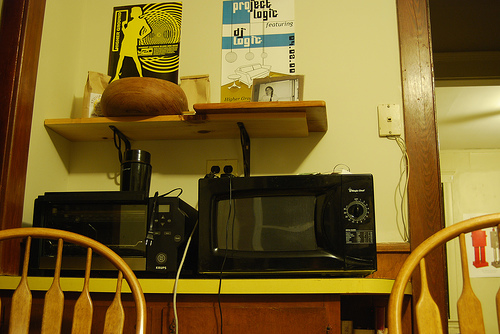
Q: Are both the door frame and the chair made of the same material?
A: Yes, both the door frame and the chair are made of wood.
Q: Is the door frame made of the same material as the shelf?
A: Yes, both the door frame and the shelf are made of wood.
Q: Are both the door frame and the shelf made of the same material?
A: Yes, both the door frame and the shelf are made of wood.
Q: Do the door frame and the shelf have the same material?
A: Yes, both the door frame and the shelf are made of wood.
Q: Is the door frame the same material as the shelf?
A: Yes, both the door frame and the shelf are made of wood.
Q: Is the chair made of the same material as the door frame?
A: Yes, both the chair and the door frame are made of wood.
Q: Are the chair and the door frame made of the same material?
A: Yes, both the chair and the door frame are made of wood.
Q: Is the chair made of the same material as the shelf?
A: Yes, both the chair and the shelf are made of wood.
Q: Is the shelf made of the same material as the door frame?
A: Yes, both the shelf and the door frame are made of wood.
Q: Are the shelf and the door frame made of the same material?
A: Yes, both the shelf and the door frame are made of wood.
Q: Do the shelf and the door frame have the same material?
A: Yes, both the shelf and the door frame are made of wood.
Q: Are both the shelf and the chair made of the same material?
A: Yes, both the shelf and the chair are made of wood.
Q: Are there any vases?
A: No, there are no vases.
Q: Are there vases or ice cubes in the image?
A: No, there are no vases or ice cubes.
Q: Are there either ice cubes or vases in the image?
A: No, there are no vases or ice cubes.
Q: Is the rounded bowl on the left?
A: Yes, the bowl is on the left of the image.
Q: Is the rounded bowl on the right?
A: No, the bowl is on the left of the image.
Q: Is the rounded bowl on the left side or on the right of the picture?
A: The bowl is on the left of the image.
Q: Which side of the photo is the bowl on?
A: The bowl is on the left of the image.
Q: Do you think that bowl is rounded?
A: Yes, the bowl is rounded.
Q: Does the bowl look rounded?
A: Yes, the bowl is rounded.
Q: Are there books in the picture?
A: No, there are no books.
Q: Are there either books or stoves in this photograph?
A: No, there are no books or stoves.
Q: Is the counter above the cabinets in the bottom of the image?
A: Yes, the counter is above the cabinets.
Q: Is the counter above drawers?
A: No, the counter is above the cabinets.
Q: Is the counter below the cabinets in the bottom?
A: No, the counter is above the cabinets.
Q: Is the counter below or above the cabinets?
A: The counter is above the cabinets.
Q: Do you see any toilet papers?
A: No, there are no toilet papers.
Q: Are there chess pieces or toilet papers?
A: No, there are no toilet papers or chess pieces.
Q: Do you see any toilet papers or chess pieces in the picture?
A: No, there are no toilet papers or chess pieces.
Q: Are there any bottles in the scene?
A: No, there are no bottles.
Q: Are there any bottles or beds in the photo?
A: No, there are no bottles or beds.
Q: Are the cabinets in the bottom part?
A: Yes, the cabinets are in the bottom of the image.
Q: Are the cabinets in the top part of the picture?
A: No, the cabinets are in the bottom of the image.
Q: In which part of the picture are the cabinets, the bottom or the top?
A: The cabinets are in the bottom of the image.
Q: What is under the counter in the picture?
A: The cabinets are under the counter.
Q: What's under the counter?
A: The cabinets are under the counter.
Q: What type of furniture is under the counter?
A: The pieces of furniture are cabinets.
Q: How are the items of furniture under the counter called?
A: The pieces of furniture are cabinets.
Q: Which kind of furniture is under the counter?
A: The pieces of furniture are cabinets.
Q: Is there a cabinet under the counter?
A: Yes, there are cabinets under the counter.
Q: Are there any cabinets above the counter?
A: No, the cabinets are under the counter.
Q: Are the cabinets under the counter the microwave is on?
A: Yes, the cabinets are under the counter.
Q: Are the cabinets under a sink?
A: No, the cabinets are under the counter.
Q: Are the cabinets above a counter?
A: No, the cabinets are under a counter.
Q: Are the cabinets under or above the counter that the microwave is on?
A: The cabinets are under the counter.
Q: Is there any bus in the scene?
A: No, there are no buses.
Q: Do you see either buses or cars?
A: No, there are no buses or cars.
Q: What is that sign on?
A: The sign is on the wall.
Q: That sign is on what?
A: The sign is on the wall.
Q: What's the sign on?
A: The sign is on the wall.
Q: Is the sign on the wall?
A: Yes, the sign is on the wall.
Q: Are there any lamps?
A: No, there are no lamps.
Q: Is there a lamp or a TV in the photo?
A: No, there are no lamps or televisions.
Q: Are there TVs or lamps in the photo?
A: No, there are no lamps or tvs.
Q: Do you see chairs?
A: Yes, there is a chair.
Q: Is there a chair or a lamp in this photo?
A: Yes, there is a chair.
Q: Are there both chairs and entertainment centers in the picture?
A: No, there is a chair but no entertainment centers.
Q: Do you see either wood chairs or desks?
A: Yes, there is a wood chair.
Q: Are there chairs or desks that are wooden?
A: Yes, the chair is wooden.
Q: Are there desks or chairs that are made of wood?
A: Yes, the chair is made of wood.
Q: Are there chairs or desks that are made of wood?
A: Yes, the chair is made of wood.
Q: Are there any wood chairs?
A: Yes, there is a wood chair.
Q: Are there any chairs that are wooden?
A: Yes, there is a chair that is wooden.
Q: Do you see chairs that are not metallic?
A: Yes, there is a wooden chair.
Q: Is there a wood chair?
A: Yes, there is a chair that is made of wood.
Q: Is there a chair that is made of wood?
A: Yes, there is a chair that is made of wood.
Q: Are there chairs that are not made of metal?
A: Yes, there is a chair that is made of wood.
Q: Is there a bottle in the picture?
A: No, there are no bottles.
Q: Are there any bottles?
A: No, there are no bottles.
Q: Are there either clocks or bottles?
A: No, there are no bottles or clocks.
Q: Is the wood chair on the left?
A: Yes, the chair is on the left of the image.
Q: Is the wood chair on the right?
A: No, the chair is on the left of the image.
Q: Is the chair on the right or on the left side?
A: The chair is on the left of the image.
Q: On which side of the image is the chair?
A: The chair is on the left of the image.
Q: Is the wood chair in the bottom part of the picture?
A: Yes, the chair is in the bottom of the image.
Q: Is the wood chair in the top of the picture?
A: No, the chair is in the bottom of the image.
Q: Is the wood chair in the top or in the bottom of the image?
A: The chair is in the bottom of the image.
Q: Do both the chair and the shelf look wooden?
A: Yes, both the chair and the shelf are wooden.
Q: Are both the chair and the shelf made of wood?
A: Yes, both the chair and the shelf are made of wood.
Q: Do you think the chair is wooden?
A: Yes, the chair is wooden.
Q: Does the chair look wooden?
A: Yes, the chair is wooden.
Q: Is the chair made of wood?
A: Yes, the chair is made of wood.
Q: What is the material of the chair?
A: The chair is made of wood.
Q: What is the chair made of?
A: The chair is made of wood.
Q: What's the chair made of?
A: The chair is made of wood.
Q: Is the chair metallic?
A: No, the chair is wooden.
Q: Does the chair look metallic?
A: No, the chair is wooden.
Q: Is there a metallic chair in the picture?
A: No, there is a chair but it is wooden.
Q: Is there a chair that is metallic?
A: No, there is a chair but it is wooden.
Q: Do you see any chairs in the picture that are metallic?
A: No, there is a chair but it is wooden.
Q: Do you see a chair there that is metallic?
A: No, there is a chair but it is wooden.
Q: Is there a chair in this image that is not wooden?
A: No, there is a chair but it is wooden.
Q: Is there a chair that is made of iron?
A: No, there is a chair but it is made of wood.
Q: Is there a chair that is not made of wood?
A: No, there is a chair but it is made of wood.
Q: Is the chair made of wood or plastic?
A: The chair is made of wood.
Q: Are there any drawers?
A: No, there are no drawers.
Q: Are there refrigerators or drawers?
A: No, there are no drawers or refrigerators.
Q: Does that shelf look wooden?
A: Yes, the shelf is wooden.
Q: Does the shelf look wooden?
A: Yes, the shelf is wooden.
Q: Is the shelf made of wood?
A: Yes, the shelf is made of wood.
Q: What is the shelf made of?
A: The shelf is made of wood.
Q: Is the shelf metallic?
A: No, the shelf is wooden.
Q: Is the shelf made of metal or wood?
A: The shelf is made of wood.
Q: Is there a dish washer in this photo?
A: No, there are no dishwashers.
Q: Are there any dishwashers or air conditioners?
A: No, there are no dishwashers or air conditioners.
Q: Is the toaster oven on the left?
A: Yes, the toaster oven is on the left of the image.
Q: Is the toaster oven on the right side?
A: No, the toaster oven is on the left of the image.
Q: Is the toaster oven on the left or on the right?
A: The toaster oven is on the left of the image.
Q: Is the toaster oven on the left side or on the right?
A: The toaster oven is on the left of the image.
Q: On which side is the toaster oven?
A: The toaster oven is on the left of the image.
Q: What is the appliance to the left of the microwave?
A: The appliance is a toaster oven.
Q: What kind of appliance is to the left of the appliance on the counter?
A: The appliance is a toaster oven.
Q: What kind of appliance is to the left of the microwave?
A: The appliance is a toaster oven.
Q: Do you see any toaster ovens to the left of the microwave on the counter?
A: Yes, there is a toaster oven to the left of the microwave.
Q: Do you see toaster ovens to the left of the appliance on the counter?
A: Yes, there is a toaster oven to the left of the microwave.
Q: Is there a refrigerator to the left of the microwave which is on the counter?
A: No, there is a toaster oven to the left of the microwave.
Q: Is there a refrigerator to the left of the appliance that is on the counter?
A: No, there is a toaster oven to the left of the microwave.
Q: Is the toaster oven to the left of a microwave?
A: Yes, the toaster oven is to the left of a microwave.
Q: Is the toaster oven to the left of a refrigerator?
A: No, the toaster oven is to the left of a microwave.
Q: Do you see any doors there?
A: Yes, there is a door.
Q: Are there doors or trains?
A: Yes, there is a door.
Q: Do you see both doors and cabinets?
A: Yes, there are both a door and a cabinet.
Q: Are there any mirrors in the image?
A: No, there are no mirrors.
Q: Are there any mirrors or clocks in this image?
A: No, there are no mirrors or clocks.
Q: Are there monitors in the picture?
A: No, there are no monitors.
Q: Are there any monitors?
A: No, there are no monitors.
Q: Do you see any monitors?
A: No, there are no monitors.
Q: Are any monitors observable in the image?
A: No, there are no monitors.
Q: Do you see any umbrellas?
A: No, there are no umbrellas.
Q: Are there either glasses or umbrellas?
A: No, there are no umbrellas or glasses.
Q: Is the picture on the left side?
A: Yes, the picture is on the left of the image.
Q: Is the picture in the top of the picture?
A: Yes, the picture is in the top of the image.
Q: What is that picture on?
A: The picture is on the wall.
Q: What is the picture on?
A: The picture is on the wall.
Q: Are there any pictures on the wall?
A: Yes, there is a picture on the wall.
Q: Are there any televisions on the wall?
A: No, there is a picture on the wall.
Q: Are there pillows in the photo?
A: No, there are no pillows.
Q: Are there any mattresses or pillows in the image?
A: No, there are no pillows or mattresses.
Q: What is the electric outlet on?
A: The electric outlet is on the wall.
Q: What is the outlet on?
A: The electric outlet is on the wall.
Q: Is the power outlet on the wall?
A: Yes, the power outlet is on the wall.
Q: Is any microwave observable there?
A: Yes, there is a microwave.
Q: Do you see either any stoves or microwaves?
A: Yes, there is a microwave.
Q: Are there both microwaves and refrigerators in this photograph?
A: No, there is a microwave but no refrigerators.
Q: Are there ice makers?
A: No, there are no ice makers.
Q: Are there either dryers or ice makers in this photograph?
A: No, there are no ice makers or dryers.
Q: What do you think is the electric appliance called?
A: The appliance is a microwave.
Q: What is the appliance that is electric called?
A: The appliance is a microwave.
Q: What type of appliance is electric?
A: The appliance is a microwave.